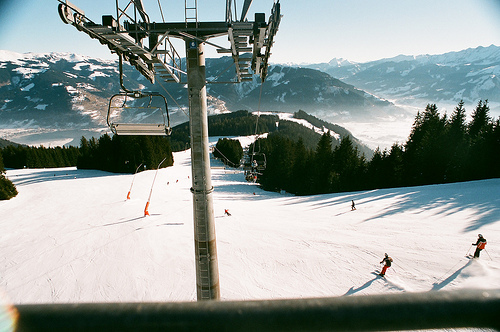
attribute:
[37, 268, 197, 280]
snow — white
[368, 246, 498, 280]
skiers — skiing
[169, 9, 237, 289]
ladder — tall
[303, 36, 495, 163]
mountains — distant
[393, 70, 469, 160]
trees — green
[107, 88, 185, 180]
seat — empty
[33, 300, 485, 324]
pole — gray, metal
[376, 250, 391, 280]
one skier — casting shadow in snow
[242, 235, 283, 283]
snow — LARGE, BODY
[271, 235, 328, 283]
snow — BODY, LARGE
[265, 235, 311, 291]
snow — LARGE, BODY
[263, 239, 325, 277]
snow — BODY, LARGE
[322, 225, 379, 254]
snow — LARGE, BODY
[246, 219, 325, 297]
snow — BODY, LARGE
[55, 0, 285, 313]
ski lift — gray 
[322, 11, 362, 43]
white clouds — white 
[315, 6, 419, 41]
blue sky — blue 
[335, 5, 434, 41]
blue sky — blue 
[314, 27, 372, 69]
clouds — white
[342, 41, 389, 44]
skys — blue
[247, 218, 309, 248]
snow — white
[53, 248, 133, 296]
snow — white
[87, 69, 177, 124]
seat — empty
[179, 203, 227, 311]
ladder — tall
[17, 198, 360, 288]
hill — snow covered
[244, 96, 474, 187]
trees — pine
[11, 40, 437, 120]
mountains — snowy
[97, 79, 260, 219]
ski lift — tall